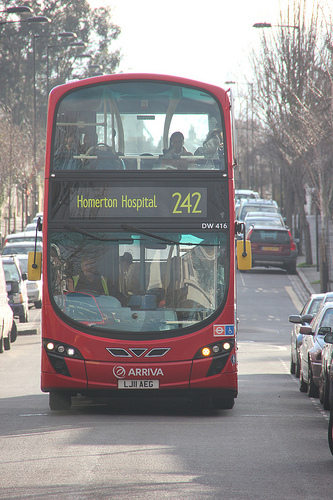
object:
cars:
[297, 290, 333, 394]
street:
[3, 269, 330, 497]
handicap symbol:
[225, 323, 235, 336]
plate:
[41, 357, 237, 392]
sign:
[69, 187, 208, 216]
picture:
[16, 406, 332, 494]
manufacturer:
[112, 364, 163, 379]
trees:
[300, 1, 331, 291]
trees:
[3, 1, 30, 231]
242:
[169, 188, 203, 217]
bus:
[23, 73, 252, 410]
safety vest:
[67, 271, 111, 295]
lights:
[200, 341, 211, 358]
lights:
[45, 338, 55, 354]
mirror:
[237, 237, 251, 271]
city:
[1, 0, 332, 496]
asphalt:
[44, 407, 276, 492]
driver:
[74, 251, 101, 288]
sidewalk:
[285, 229, 332, 310]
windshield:
[46, 231, 232, 337]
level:
[36, 72, 233, 177]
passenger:
[58, 125, 85, 156]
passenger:
[81, 126, 106, 152]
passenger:
[156, 126, 197, 162]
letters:
[75, 193, 160, 211]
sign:
[196, 217, 229, 233]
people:
[55, 113, 213, 301]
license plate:
[117, 378, 160, 389]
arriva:
[127, 365, 166, 379]